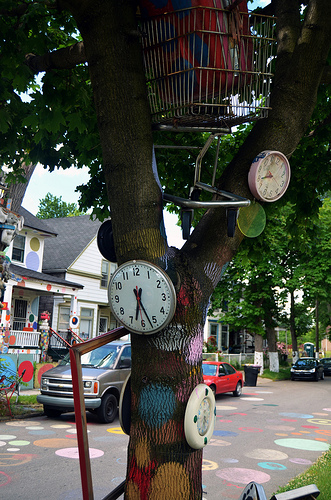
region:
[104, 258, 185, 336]
numerical clock hanging on tree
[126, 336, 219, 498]
white clock hanging on tree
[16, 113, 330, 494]
a tree full of clocks and a shopping basket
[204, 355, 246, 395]
red car parked on side of road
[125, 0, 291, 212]
shopping basket up in tree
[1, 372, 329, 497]
street covered with circles of chock and paint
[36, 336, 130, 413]
silver van parked on side of street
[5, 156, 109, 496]
a white house across the street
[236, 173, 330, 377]
bunch of trees across street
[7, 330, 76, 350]
white house with stairs and railing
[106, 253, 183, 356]
clock has metal rim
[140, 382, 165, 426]
blue spot on tree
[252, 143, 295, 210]
clock is pink and plastic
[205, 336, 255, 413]
red car behind tree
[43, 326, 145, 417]
silver van behind tree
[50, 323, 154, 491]
red picture frame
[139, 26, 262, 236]
metal shopping cart in tree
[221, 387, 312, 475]
colorful circles on street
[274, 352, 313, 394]
black car in distance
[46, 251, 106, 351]
house with white siding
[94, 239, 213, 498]
Clock posted on a tree.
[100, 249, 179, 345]
The clock is round.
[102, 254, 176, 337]
The clock has black numbers.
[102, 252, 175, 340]
Clock has black hands.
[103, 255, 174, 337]
The second hand is red.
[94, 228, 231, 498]
Colorful spots on a tree.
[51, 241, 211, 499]
Picture frame on a tree.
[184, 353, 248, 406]
Red car is parked.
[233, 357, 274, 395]
The trash can is black.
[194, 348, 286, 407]
Trash can at end of driveway.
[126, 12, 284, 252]
silver shopping basket in a tree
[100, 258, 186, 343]
clock on a tree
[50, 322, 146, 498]
red picture frame on a tree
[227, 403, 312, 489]
circles painted on the street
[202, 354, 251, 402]
red car parked on street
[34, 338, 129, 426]
grey van parked on street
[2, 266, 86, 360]
circles painted on a white house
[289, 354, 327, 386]
black car parked on street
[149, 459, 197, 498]
yellow circle painted on a tree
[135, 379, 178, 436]
blue circle painted on a tree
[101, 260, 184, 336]
Clock on a painted tree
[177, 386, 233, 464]
Clock on a painted tree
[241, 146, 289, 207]
Clock on a tree trunk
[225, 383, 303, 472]
Paint on the street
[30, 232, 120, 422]
Silver van parked in front of houses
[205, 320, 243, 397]
Red car in front of houses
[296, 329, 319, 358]
Don's John in front of houses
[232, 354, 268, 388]
Trash can in the road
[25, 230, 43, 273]
Circles painted on a house.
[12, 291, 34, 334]
White screen door on house